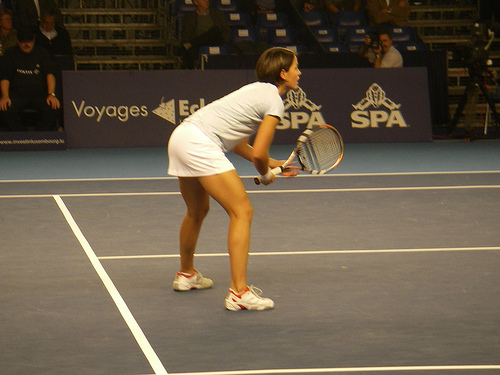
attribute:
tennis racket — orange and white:
[253, 122, 344, 187]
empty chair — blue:
[228, 10, 242, 29]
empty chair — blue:
[234, 28, 252, 49]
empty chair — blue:
[274, 26, 290, 42]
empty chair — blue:
[264, 11, 277, 29]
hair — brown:
[255, 40, 295, 78]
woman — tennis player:
[157, 42, 315, 318]